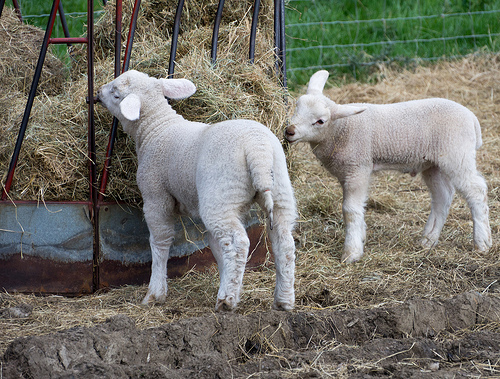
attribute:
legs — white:
[157, 171, 490, 298]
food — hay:
[50, 38, 185, 180]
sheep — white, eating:
[281, 66, 496, 263]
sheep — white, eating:
[95, 67, 299, 313]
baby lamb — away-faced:
[97, 69, 298, 309]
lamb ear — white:
[158, 73, 200, 105]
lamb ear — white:
[113, 88, 143, 125]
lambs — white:
[98, 68, 492, 312]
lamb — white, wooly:
[99, 56, 313, 334]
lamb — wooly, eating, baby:
[285, 69, 493, 261]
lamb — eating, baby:
[99, 70, 296, 309]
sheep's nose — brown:
[281, 122, 298, 141]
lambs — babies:
[77, 53, 494, 303]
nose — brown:
[279, 122, 299, 137]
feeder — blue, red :
[6, 2, 291, 272]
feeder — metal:
[26, 2, 280, 292]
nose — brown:
[93, 85, 115, 110]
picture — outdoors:
[3, 0, 499, 375]